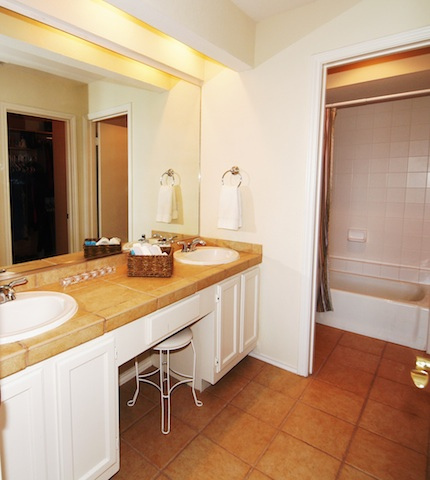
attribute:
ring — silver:
[217, 163, 244, 190]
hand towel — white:
[217, 184, 241, 228]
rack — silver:
[222, 164, 242, 187]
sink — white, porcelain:
[5, 294, 220, 335]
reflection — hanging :
[343, 159, 428, 200]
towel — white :
[213, 184, 253, 231]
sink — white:
[174, 244, 239, 266]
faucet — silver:
[175, 237, 206, 252]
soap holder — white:
[338, 213, 379, 243]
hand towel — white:
[215, 186, 243, 233]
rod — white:
[324, 86, 426, 114]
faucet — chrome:
[0, 274, 30, 301]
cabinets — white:
[217, 271, 257, 369]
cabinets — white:
[61, 361, 119, 477]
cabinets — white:
[3, 369, 50, 477]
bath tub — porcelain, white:
[315, 267, 429, 352]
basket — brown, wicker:
[127, 236, 181, 275]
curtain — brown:
[315, 103, 337, 311]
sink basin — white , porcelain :
[174, 243, 239, 264]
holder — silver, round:
[219, 162, 242, 187]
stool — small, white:
[125, 325, 202, 434]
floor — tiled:
[112, 320, 428, 479]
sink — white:
[172, 241, 243, 266]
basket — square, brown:
[125, 244, 177, 279]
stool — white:
[128, 330, 206, 435]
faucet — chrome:
[177, 237, 202, 251]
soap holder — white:
[347, 227, 368, 241]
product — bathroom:
[130, 242, 144, 253]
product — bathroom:
[139, 240, 157, 255]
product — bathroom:
[153, 241, 160, 255]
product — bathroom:
[160, 249, 168, 256]